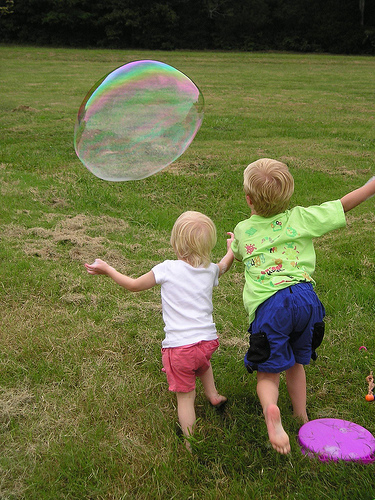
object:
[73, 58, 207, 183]
bubble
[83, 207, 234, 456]
girl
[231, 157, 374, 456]
boy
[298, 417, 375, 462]
frisbee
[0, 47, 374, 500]
grass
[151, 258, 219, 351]
shirt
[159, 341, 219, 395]
shorts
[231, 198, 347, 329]
tshirt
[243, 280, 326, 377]
shorts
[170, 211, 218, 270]
hair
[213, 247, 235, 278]
arm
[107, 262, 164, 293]
arm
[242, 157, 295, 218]
hair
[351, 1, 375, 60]
trees